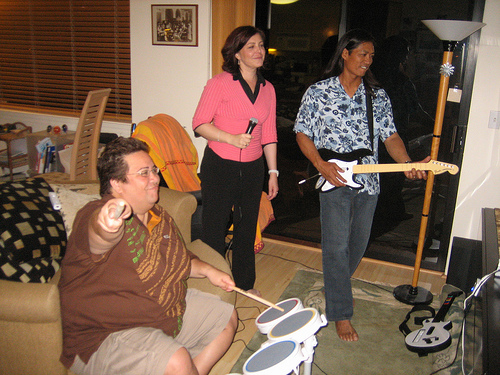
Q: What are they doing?
A: Playing music.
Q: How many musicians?
A: 3.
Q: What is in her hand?
A: A microphone.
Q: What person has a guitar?
A: The dark skinned man.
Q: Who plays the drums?
A: The man with glasses.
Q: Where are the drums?
A: On the floor.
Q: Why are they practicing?
A: Karaoke.